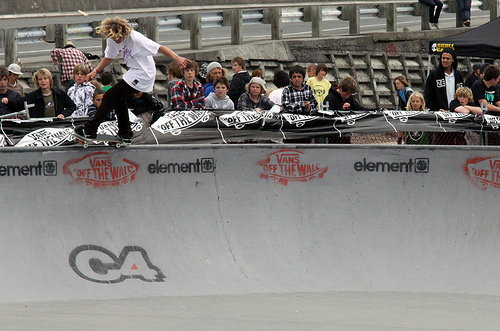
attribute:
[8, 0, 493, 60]
road — paved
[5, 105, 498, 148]
banner — black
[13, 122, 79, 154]
decals — white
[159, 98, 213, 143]
decals — white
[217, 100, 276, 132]
decals — white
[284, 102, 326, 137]
decals — white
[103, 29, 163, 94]
shirt — white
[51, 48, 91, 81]
shirt — plaid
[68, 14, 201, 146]
male — blond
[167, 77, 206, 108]
plaid shirt — black, white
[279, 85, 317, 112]
plaid shirt — black, white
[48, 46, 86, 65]
plaid shirt — black, white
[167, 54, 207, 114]
boy — young, red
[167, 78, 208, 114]
shirt — black, plaid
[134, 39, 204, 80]
hair — dark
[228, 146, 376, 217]
vans — off the wall, sponsor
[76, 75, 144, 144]
legs — sets, in upper right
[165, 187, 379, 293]
ramp — concrete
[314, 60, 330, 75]
hair — dark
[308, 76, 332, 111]
shirt — yellow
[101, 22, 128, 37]
boy — sitting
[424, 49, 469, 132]
man — standing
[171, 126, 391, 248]
ramp — gray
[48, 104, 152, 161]
skateboard — concrete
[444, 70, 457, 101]
shirt — white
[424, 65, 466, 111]
jacket — black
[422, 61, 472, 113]
coat — black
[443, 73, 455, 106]
shirt — white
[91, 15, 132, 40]
hair — brown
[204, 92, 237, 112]
sweatshirt — gray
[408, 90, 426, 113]
hair — blonde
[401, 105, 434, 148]
shirt — green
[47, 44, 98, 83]
shirt — flannel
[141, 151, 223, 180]
name — element, brand